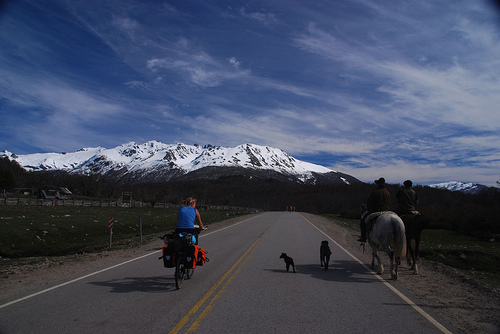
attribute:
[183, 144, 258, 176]
mountains — snowy, snow covered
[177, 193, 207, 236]
woman — riding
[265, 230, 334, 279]
dogs — walking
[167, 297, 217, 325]
lines — yellow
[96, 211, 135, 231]
grass — green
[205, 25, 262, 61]
sky — blue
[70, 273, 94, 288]
lines — white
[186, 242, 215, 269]
tag — red, orange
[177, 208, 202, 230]
shirt — blue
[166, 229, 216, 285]
bike — small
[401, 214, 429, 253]
animal — large, brown, walking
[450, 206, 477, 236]
bushes — green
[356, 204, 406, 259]
horse — white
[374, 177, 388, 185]
hat — black